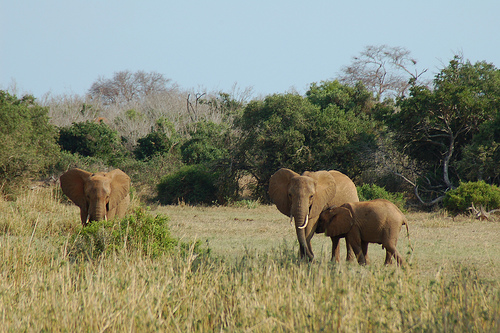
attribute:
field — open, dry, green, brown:
[0, 204, 496, 333]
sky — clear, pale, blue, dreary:
[0, 0, 498, 104]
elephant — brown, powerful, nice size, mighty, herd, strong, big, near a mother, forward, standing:
[61, 167, 136, 227]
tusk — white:
[85, 215, 91, 226]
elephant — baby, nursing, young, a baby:
[315, 199, 409, 272]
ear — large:
[61, 168, 87, 208]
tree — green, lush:
[57, 120, 114, 159]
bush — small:
[445, 179, 497, 220]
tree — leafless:
[81, 70, 186, 144]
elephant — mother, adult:
[268, 168, 360, 264]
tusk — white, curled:
[296, 216, 310, 230]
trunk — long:
[292, 205, 314, 262]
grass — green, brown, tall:
[0, 236, 498, 332]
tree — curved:
[364, 107, 459, 209]